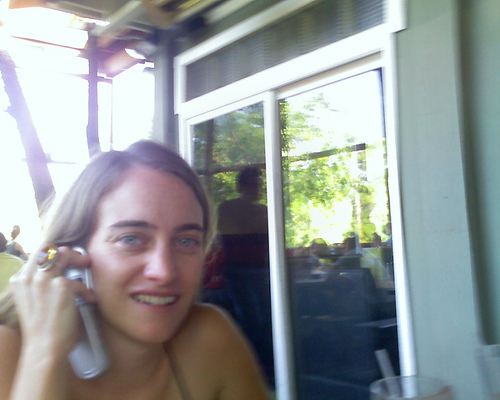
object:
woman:
[1, 135, 274, 399]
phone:
[52, 245, 117, 383]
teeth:
[151, 295, 166, 303]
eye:
[111, 230, 152, 250]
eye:
[168, 232, 203, 252]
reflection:
[202, 163, 270, 373]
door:
[173, 48, 418, 399]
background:
[1, 0, 500, 399]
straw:
[372, 346, 401, 399]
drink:
[366, 373, 456, 399]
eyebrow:
[105, 218, 159, 232]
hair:
[0, 136, 220, 329]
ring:
[33, 248, 64, 275]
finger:
[32, 245, 92, 280]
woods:
[0, 48, 57, 234]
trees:
[193, 93, 384, 250]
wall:
[392, 0, 500, 400]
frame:
[171, 0, 419, 399]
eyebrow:
[172, 221, 206, 233]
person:
[1, 230, 26, 296]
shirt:
[0, 250, 25, 295]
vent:
[180, 1, 389, 103]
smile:
[125, 288, 185, 316]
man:
[209, 165, 289, 347]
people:
[323, 238, 363, 284]